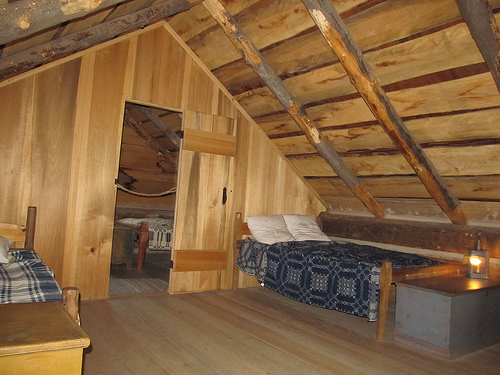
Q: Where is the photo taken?
A: Cabin.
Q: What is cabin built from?
A: Wood.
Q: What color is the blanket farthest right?
A: Blue.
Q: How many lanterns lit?
A: 1.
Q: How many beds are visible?
A: 3.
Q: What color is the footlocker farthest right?
A: Grey.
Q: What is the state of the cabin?
A: Clean.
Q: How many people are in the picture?
A: Zero.